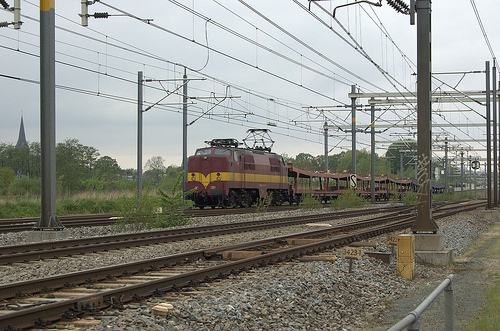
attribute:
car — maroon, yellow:
[184, 137, 301, 206]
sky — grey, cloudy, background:
[1, 2, 498, 177]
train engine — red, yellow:
[183, 136, 288, 209]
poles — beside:
[26, 0, 467, 195]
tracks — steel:
[2, 194, 499, 329]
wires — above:
[198, 14, 417, 96]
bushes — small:
[133, 187, 200, 226]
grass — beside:
[3, 192, 187, 217]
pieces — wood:
[234, 221, 408, 271]